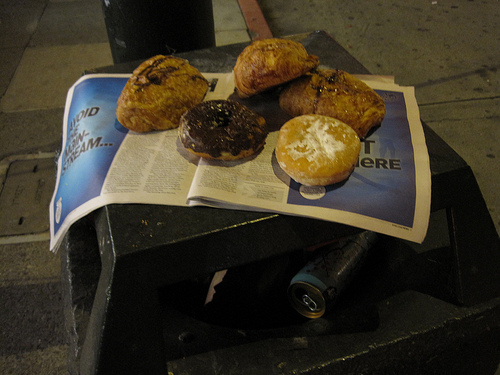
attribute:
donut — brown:
[229, 33, 321, 103]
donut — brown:
[114, 49, 213, 136]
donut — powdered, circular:
[272, 110, 363, 191]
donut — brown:
[272, 60, 388, 144]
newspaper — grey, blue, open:
[43, 68, 437, 258]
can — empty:
[282, 222, 385, 319]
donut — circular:
[171, 94, 272, 168]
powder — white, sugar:
[291, 117, 347, 167]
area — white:
[104, 73, 289, 204]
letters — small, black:
[124, 143, 157, 155]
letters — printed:
[160, 156, 188, 168]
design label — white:
[55, 197, 63, 224]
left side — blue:
[52, 77, 130, 235]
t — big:
[360, 138, 376, 154]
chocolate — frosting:
[180, 100, 268, 158]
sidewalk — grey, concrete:
[0, 1, 251, 375]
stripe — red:
[236, 0, 274, 40]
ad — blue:
[286, 92, 416, 228]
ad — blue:
[53, 77, 131, 236]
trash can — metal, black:
[61, 29, 498, 374]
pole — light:
[101, 1, 219, 63]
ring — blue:
[290, 273, 331, 298]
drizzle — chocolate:
[137, 58, 178, 93]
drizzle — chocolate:
[311, 69, 344, 114]